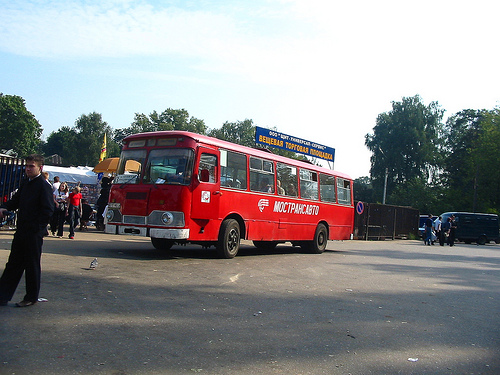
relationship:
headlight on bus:
[159, 211, 173, 224] [102, 132, 355, 247]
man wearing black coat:
[0, 154, 58, 307] [5, 175, 62, 240]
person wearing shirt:
[53, 176, 71, 236] [52, 189, 69, 209]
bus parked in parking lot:
[102, 132, 355, 247] [0, 224, 495, 373]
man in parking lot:
[0, 154, 58, 307] [0, 224, 495, 373]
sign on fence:
[354, 199, 367, 215] [352, 198, 418, 240]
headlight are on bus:
[105, 208, 115, 221] [110, 131, 260, 235]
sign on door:
[196, 186, 215, 205] [189, 139, 225, 221]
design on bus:
[257, 197, 268, 209] [102, 132, 355, 247]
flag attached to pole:
[93, 131, 106, 166] [103, 128, 110, 157]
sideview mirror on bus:
[198, 166, 210, 182] [101, 127, 357, 264]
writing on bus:
[256, 199, 336, 219] [101, 127, 357, 264]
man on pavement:
[13, 147, 55, 212] [13, 309, 70, 337]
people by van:
[422, 213, 458, 245] [425, 212, 499, 243]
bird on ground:
[87, 255, 102, 270] [10, 222, 498, 372]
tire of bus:
[218, 217, 240, 257] [102, 132, 355, 247]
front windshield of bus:
[150, 149, 195, 181] [102, 132, 355, 247]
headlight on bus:
[159, 209, 173, 231] [101, 127, 357, 264]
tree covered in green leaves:
[371, 93, 438, 158] [367, 90, 470, 196]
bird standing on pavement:
[82, 255, 101, 272] [292, 271, 432, 341]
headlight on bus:
[102, 206, 127, 229] [85, 115, 365, 262]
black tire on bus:
[201, 212, 313, 248] [102, 132, 355, 247]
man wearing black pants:
[0, 154, 58, 307] [3, 232, 42, 297]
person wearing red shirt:
[68, 185, 85, 242] [71, 191, 79, 206]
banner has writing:
[244, 120, 340, 176] [258, 130, 333, 165]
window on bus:
[152, 149, 187, 184] [121, 135, 363, 238]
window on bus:
[197, 136, 272, 203] [83, 123, 448, 287]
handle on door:
[210, 183, 225, 194] [181, 125, 224, 223]